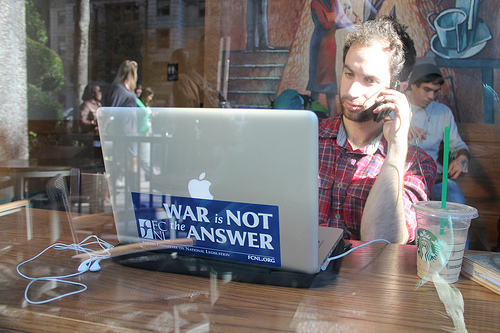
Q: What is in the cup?
A: Coffee.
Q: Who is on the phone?
A: A man.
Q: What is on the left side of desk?
A: Earphones.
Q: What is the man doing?
A: Talking on the phone.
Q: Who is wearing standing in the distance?
A: A woman.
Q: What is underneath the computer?
A: A wooden table.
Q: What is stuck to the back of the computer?
A: A sticker.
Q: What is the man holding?
A: Cell phone.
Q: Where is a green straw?
A: In a cup.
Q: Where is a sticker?
A: On laptop.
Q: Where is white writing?
A: On blue sticker.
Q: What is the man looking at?
A: Laptop computer.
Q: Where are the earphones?
A: On table.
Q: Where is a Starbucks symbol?
A: On the cup.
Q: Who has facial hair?
A: Man holding cell phone.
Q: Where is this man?
A: Coffee shop.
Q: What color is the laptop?
A: Silver.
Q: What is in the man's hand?
A: Cellphone.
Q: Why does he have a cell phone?
A: Communicate.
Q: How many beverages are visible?
A: One.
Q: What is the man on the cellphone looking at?
A: Laptop.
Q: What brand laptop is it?
A: Apple.